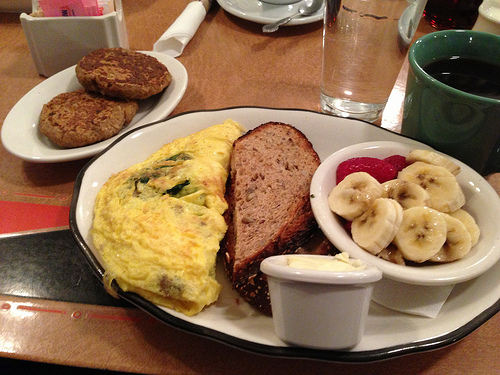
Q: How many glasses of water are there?
A: One.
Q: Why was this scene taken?
A: For a magazine.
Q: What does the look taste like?
A: Salty.